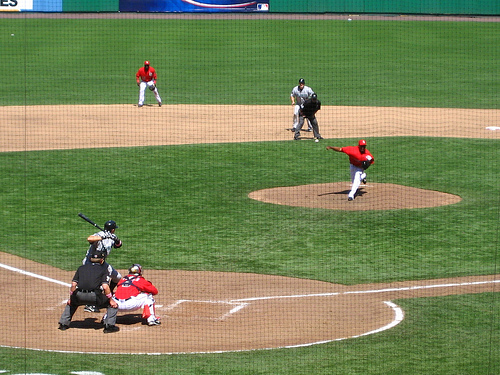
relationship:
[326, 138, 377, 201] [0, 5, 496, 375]
man delivers field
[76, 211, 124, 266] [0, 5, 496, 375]
batter anticipates field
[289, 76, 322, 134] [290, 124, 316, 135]
runner at plate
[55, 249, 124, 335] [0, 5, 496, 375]
umpire prepares for field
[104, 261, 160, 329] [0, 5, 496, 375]
catcher ready for field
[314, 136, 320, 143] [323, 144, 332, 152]
baseball leaves hand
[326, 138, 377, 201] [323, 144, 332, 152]
man has hand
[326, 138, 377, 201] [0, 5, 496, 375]
man delievers field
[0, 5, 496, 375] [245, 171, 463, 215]
field from mound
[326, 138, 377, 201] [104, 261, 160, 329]
man batters catcher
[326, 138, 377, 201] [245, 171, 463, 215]
man on mound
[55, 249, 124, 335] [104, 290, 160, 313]
umpire behind plate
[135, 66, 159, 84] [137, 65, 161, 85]
catcher for red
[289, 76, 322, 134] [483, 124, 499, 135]
runner off base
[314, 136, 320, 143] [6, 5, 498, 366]
baseball in air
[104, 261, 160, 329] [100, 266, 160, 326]
catcher in position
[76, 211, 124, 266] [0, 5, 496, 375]
batter ready for field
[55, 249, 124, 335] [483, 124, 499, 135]
umpire between base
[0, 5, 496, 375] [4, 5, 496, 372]
field on field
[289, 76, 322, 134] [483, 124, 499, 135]
player between base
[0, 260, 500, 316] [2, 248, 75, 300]
line has part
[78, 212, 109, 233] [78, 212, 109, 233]
bat has bat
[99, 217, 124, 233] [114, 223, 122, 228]
helmet has part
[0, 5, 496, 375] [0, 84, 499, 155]
field has part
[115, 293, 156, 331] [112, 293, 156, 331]
trouser has part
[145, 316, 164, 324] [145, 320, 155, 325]
shoe has part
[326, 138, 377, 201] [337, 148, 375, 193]
man in uniform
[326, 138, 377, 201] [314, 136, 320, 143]
man pitching baseball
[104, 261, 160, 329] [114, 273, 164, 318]
catcher in uniform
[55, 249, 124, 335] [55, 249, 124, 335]
umpire in uniform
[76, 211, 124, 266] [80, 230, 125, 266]
batter in uniform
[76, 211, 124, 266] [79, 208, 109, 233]
man holding bat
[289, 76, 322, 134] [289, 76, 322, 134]
runner in front of man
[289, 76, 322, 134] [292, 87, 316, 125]
man in uniform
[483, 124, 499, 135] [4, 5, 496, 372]
base on field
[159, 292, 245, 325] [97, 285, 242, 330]
marking on base